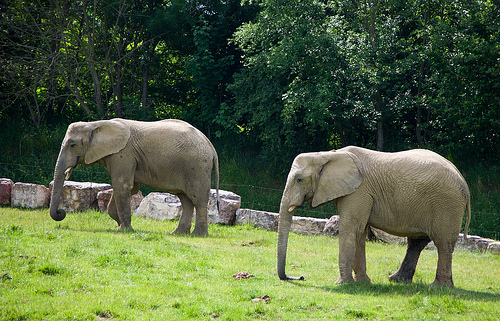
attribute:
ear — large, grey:
[85, 120, 130, 164]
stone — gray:
[11, 176, 49, 216]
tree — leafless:
[1, 0, 199, 115]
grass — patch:
[10, 179, 479, 319]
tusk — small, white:
[272, 202, 312, 219]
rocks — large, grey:
[9, 180, 50, 207]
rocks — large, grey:
[180, 188, 241, 224]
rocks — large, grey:
[46, 177, 111, 212]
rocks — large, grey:
[206, 187, 240, 224]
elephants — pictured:
[280, 143, 472, 290]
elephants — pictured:
[49, 118, 220, 241]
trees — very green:
[4, 0, 496, 174]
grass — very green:
[22, 243, 265, 313]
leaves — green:
[330, 28, 460, 107]